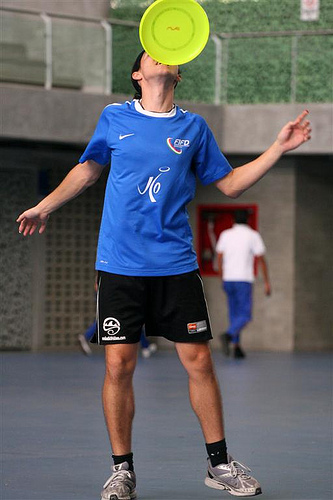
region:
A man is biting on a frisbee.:
[18, 3, 308, 494]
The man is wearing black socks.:
[90, 430, 275, 491]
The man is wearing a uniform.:
[72, 41, 256, 493]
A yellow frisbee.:
[134, 1, 214, 64]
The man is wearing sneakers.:
[88, 448, 261, 494]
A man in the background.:
[213, 199, 271, 356]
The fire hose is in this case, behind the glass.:
[190, 194, 259, 273]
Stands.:
[0, 4, 90, 129]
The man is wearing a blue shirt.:
[71, 84, 222, 284]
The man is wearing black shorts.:
[82, 264, 227, 357]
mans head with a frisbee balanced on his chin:
[110, 2, 218, 102]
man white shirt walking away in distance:
[208, 213, 269, 363]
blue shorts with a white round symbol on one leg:
[84, 261, 217, 346]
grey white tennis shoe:
[193, 449, 268, 491]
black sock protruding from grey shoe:
[195, 436, 237, 464]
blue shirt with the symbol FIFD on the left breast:
[83, 93, 233, 283]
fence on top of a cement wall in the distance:
[225, 27, 332, 111]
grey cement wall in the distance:
[281, 249, 326, 346]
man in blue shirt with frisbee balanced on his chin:
[62, 35, 246, 280]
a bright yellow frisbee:
[137, 0, 210, 66]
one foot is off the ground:
[203, 451, 266, 498]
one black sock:
[201, 437, 229, 467]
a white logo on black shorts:
[99, 315, 130, 345]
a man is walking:
[211, 208, 272, 356]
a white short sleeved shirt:
[215, 224, 266, 283]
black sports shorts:
[89, 259, 213, 346]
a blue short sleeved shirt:
[78, 95, 234, 277]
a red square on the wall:
[193, 200, 261, 281]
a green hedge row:
[104, 3, 332, 106]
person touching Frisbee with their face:
[133, 0, 212, 68]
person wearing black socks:
[103, 434, 226, 462]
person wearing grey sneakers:
[97, 460, 261, 495]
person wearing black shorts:
[87, 267, 219, 338]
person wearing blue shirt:
[78, 99, 230, 273]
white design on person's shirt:
[131, 158, 171, 208]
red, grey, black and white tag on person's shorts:
[178, 315, 211, 338]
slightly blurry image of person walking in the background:
[208, 201, 279, 361]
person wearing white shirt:
[217, 218, 265, 280]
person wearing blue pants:
[215, 278, 260, 341]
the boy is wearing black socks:
[103, 435, 229, 473]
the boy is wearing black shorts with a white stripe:
[88, 264, 215, 350]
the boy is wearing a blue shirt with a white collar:
[77, 96, 234, 279]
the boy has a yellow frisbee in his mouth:
[137, 0, 210, 65]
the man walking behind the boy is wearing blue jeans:
[221, 278, 254, 347]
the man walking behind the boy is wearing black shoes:
[217, 330, 248, 360]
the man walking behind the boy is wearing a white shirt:
[216, 222, 268, 282]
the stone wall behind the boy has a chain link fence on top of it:
[0, 5, 332, 103]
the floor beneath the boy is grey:
[0, 343, 332, 498]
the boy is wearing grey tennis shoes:
[96, 460, 267, 498]